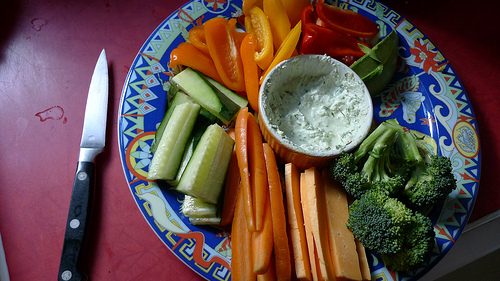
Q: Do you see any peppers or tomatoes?
A: Yes, there is a pepper.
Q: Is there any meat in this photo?
A: No, there is no meat.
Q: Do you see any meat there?
A: No, there is no meat.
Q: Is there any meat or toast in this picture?
A: No, there are no meat or toasts.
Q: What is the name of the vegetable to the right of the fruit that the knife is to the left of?
A: The vegetable is a pepper.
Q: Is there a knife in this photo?
A: Yes, there is a knife.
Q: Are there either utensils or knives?
A: Yes, there is a knife.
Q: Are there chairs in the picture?
A: No, there are no chairs.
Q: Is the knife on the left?
A: Yes, the knife is on the left of the image.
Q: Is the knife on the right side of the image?
A: No, the knife is on the left of the image.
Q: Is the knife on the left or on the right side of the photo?
A: The knife is on the left of the image.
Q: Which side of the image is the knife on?
A: The knife is on the left of the image.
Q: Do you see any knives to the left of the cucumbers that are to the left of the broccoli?
A: Yes, there is a knife to the left of the cucumbers.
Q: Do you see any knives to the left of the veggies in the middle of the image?
A: Yes, there is a knife to the left of the cucumbers.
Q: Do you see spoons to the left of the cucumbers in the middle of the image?
A: No, there is a knife to the left of the cucumbers.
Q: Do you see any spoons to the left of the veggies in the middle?
A: No, there is a knife to the left of the cucumbers.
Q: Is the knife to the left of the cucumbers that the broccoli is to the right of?
A: Yes, the knife is to the left of the cucumbers.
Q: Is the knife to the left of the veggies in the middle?
A: Yes, the knife is to the left of the cucumbers.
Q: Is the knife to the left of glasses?
A: No, the knife is to the left of the cucumbers.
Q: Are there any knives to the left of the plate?
A: Yes, there is a knife to the left of the plate.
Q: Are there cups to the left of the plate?
A: No, there is a knife to the left of the plate.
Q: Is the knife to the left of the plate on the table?
A: Yes, the knife is to the left of the plate.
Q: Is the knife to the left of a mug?
A: No, the knife is to the left of the plate.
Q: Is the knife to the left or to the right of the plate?
A: The knife is to the left of the plate.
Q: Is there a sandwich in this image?
A: No, there are no sandwiches.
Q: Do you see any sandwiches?
A: No, there are no sandwiches.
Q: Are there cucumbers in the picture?
A: Yes, there are cucumbers.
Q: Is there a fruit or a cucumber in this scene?
A: Yes, there are cucumbers.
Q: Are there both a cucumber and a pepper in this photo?
A: Yes, there are both a cucumber and a pepper.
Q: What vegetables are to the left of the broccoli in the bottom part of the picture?
A: The vegetables are cucumbers.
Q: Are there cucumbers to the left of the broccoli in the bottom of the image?
A: Yes, there are cucumbers to the left of the broccoli.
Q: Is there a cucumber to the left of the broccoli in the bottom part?
A: Yes, there are cucumbers to the left of the broccoli.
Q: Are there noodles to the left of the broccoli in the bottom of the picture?
A: No, there are cucumbers to the left of the broccoli.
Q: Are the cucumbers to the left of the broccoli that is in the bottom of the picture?
A: Yes, the cucumbers are to the left of the broccoli.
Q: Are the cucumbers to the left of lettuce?
A: No, the cucumbers are to the left of the broccoli.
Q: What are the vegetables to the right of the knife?
A: The vegetables are cucumbers.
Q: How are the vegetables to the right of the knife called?
A: The vegetables are cucumbers.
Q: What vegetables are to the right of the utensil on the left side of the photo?
A: The vegetables are cucumbers.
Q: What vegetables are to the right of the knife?
A: The vegetables are cucumbers.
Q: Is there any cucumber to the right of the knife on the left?
A: Yes, there are cucumbers to the right of the knife.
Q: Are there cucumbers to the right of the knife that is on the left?
A: Yes, there are cucumbers to the right of the knife.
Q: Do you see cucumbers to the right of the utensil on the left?
A: Yes, there are cucumbers to the right of the knife.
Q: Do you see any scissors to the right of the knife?
A: No, there are cucumbers to the right of the knife.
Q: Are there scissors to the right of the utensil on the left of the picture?
A: No, there are cucumbers to the right of the knife.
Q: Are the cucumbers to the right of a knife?
A: Yes, the cucumbers are to the right of a knife.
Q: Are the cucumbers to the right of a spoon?
A: No, the cucumbers are to the right of a knife.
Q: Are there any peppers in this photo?
A: Yes, there are peppers.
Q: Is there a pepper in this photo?
A: Yes, there are peppers.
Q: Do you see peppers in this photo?
A: Yes, there are peppers.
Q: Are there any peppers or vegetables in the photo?
A: Yes, there are peppers.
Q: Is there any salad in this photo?
A: No, there is no salad.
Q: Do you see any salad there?
A: No, there is no salad.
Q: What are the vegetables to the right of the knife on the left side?
A: The vegetables are peppers.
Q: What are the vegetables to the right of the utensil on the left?
A: The vegetables are peppers.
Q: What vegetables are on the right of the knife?
A: The vegetables are peppers.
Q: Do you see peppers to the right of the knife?
A: Yes, there are peppers to the right of the knife.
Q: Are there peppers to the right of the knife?
A: Yes, there are peppers to the right of the knife.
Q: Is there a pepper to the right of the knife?
A: Yes, there are peppers to the right of the knife.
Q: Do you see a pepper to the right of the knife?
A: Yes, there are peppers to the right of the knife.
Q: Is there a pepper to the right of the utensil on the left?
A: Yes, there are peppers to the right of the knife.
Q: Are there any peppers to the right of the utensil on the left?
A: Yes, there are peppers to the right of the knife.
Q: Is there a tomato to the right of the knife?
A: No, there are peppers to the right of the knife.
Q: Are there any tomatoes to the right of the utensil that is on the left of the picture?
A: No, there are peppers to the right of the knife.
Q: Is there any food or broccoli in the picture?
A: Yes, there is broccoli.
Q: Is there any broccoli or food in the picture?
A: Yes, there is broccoli.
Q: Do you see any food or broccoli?
A: Yes, there is broccoli.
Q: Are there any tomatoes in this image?
A: No, there are no tomatoes.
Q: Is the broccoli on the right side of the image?
A: Yes, the broccoli is on the right of the image.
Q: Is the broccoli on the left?
A: No, the broccoli is on the right of the image.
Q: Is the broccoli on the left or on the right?
A: The broccoli is on the right of the image.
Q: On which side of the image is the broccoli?
A: The broccoli is on the right of the image.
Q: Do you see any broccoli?
A: Yes, there is broccoli.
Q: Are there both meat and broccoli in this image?
A: No, there is broccoli but no meat.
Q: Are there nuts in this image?
A: No, there are no nuts.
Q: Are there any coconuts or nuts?
A: No, there are no nuts or coconuts.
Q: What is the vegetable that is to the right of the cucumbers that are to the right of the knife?
A: The vegetable is broccoli.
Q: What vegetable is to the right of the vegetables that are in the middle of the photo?
A: The vegetable is broccoli.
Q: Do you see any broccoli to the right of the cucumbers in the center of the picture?
A: Yes, there is broccoli to the right of the cucumbers.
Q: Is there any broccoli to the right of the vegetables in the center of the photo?
A: Yes, there is broccoli to the right of the cucumbers.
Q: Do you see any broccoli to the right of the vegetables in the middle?
A: Yes, there is broccoli to the right of the cucumbers.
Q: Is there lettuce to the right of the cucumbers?
A: No, there is broccoli to the right of the cucumbers.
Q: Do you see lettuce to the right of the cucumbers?
A: No, there is broccoli to the right of the cucumbers.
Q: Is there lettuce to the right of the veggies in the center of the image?
A: No, there is broccoli to the right of the cucumbers.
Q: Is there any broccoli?
A: Yes, there is broccoli.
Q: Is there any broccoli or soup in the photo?
A: Yes, there is broccoli.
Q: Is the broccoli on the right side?
A: Yes, the broccoli is on the right of the image.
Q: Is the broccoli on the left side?
A: No, the broccoli is on the right of the image.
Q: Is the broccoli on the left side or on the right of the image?
A: The broccoli is on the right of the image.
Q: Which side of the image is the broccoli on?
A: The broccoli is on the right of the image.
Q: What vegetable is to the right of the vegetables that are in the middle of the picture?
A: The vegetable is broccoli.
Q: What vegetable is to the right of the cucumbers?
A: The vegetable is broccoli.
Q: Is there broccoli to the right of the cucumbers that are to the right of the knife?
A: Yes, there is broccoli to the right of the cucumbers.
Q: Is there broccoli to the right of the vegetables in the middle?
A: Yes, there is broccoli to the right of the cucumbers.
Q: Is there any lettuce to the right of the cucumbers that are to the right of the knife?
A: No, there is broccoli to the right of the cucumbers.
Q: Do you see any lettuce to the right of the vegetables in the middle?
A: No, there is broccoli to the right of the cucumbers.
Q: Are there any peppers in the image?
A: Yes, there is a pepper.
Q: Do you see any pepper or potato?
A: Yes, there is a pepper.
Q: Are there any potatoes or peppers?
A: Yes, there is a pepper.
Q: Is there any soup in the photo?
A: No, there is no soup.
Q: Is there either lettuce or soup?
A: No, there are no soup or lettuce.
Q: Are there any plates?
A: Yes, there is a plate.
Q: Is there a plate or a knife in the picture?
A: Yes, there is a plate.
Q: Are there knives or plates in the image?
A: Yes, there is a plate.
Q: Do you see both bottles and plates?
A: No, there is a plate but no bottles.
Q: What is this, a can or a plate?
A: This is a plate.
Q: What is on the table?
A: The plate is on the table.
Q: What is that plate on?
A: The plate is on the table.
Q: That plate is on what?
A: The plate is on the table.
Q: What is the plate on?
A: The plate is on the table.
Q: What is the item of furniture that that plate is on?
A: The piece of furniture is a table.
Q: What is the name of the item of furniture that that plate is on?
A: The piece of furniture is a table.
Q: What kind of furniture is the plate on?
A: The plate is on the table.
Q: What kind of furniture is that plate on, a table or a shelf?
A: The plate is on a table.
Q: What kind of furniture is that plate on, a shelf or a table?
A: The plate is on a table.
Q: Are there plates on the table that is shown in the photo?
A: Yes, there is a plate on the table.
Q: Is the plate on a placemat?
A: No, the plate is on the table.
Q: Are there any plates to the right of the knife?
A: Yes, there is a plate to the right of the knife.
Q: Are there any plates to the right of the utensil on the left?
A: Yes, there is a plate to the right of the knife.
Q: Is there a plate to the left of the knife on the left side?
A: No, the plate is to the right of the knife.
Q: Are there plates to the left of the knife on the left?
A: No, the plate is to the right of the knife.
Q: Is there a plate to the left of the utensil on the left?
A: No, the plate is to the right of the knife.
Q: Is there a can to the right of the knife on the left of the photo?
A: No, there is a plate to the right of the knife.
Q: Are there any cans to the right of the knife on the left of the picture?
A: No, there is a plate to the right of the knife.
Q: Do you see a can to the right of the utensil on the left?
A: No, there is a plate to the right of the knife.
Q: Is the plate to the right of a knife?
A: Yes, the plate is to the right of a knife.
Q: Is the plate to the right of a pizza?
A: No, the plate is to the right of a knife.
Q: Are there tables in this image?
A: Yes, there is a table.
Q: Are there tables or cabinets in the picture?
A: Yes, there is a table.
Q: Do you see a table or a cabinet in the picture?
A: Yes, there is a table.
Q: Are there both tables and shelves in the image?
A: No, there is a table but no shelves.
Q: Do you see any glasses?
A: No, there are no glasses.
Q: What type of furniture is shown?
A: The furniture is a table.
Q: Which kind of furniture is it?
A: The piece of furniture is a table.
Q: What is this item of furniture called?
A: This is a table.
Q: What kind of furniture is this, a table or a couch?
A: This is a table.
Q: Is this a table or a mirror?
A: This is a table.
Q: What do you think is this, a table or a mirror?
A: This is a table.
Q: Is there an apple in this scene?
A: No, there are no apples.